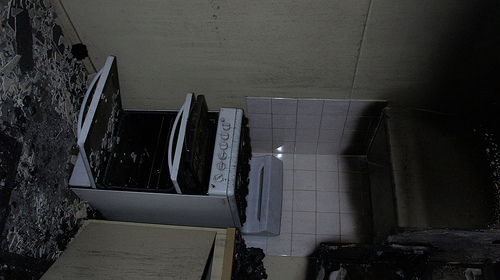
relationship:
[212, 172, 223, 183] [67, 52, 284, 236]
knob on stove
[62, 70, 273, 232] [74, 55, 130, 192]
oven has door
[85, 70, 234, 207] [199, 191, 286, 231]
stove with doors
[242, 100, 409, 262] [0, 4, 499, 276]
wall in kitchen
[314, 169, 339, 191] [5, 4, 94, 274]
tile on floor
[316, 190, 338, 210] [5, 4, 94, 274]
tile on floor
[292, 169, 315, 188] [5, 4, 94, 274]
tile on floor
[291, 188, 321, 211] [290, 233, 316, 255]
tile on tile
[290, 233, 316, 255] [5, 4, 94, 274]
tile on floor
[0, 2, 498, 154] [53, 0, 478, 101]
wall stained with grime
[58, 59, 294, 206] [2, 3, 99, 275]
stove leaning against tile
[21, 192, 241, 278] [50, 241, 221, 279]
cabinet with streaks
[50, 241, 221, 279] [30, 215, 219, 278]
streaks on door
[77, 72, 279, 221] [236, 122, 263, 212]
oven with burners